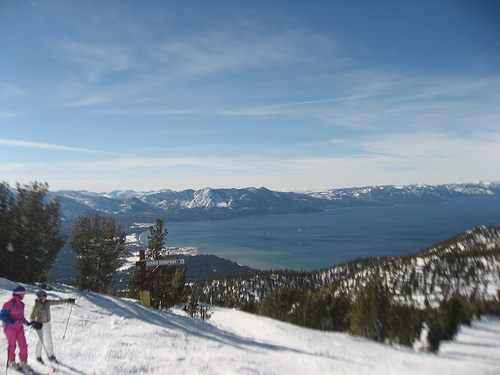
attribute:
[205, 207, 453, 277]
ocean — large, massive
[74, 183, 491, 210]
mountains — snowy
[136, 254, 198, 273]
sign — white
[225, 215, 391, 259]
water — cold, blue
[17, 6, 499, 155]
sky — blue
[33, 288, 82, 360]
woman — pointing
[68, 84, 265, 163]
clouds — white